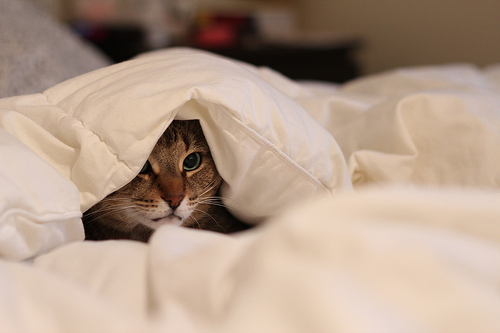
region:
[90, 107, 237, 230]
a cat under a blanket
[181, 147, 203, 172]
a left eye of a cat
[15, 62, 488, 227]
a fluffy white blanket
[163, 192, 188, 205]
a nose on a cat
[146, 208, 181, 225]
a mouth on a cat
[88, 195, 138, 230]
white whisker on a cat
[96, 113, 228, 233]
a tan and black cat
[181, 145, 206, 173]
a green left eye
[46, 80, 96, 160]
a seam in the black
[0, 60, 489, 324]
a cat hiding under a white blanket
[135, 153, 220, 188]
The eyes of the cat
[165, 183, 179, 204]
The nose of the cat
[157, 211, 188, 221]
The mouth of the cat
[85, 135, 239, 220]
The cats head poking out of the blanket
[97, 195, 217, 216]
The whiskers of the cat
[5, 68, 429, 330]
A fluffy white blanket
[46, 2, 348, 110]
objects that are out of focus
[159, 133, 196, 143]
The stripes on the cats head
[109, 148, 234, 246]
A brown tabby cat hiding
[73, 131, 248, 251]
A cat that look angry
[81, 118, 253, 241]
a cat is hiding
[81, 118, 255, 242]
cat under a blanket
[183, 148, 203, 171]
eye of a cat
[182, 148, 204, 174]
the eye is blue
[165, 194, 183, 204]
nose of a cat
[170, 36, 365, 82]
desk in the background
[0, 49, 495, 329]
the blanket is white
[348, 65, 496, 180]
wrinkles in the blanket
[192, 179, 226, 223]
the whiskers are white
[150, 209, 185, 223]
the mouth is closed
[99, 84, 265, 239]
cat in the sheets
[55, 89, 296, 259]
cat under the covers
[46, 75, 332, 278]
cute cat under the covers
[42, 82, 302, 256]
nice cat under the covers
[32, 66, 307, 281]
cuddly cat under the covers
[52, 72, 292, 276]
sweet cat under the covers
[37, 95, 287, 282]
attractive cat under the covers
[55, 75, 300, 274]
quiet cat under the covers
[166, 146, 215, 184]
eye of a cat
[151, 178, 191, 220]
nose of a cat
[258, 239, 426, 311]
piece of white sheet